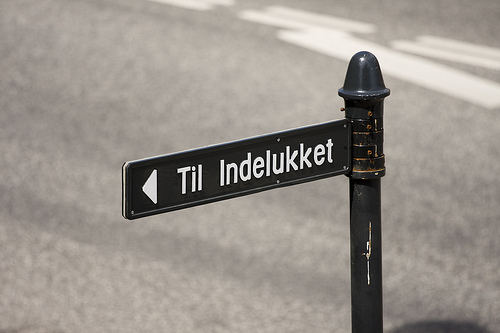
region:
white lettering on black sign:
[97, 103, 345, 235]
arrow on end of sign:
[110, 115, 340, 215]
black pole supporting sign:
[330, 40, 385, 326]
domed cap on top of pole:
[320, 45, 392, 100]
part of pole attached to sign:
[331, 82, 386, 183]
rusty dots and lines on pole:
[340, 90, 387, 180]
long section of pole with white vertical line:
[340, 172, 390, 327]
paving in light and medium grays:
[62, 30, 227, 125]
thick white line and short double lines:
[187, 2, 492, 117]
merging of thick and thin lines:
[198, 5, 394, 53]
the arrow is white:
[148, 163, 153, 221]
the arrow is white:
[138, 168, 157, 203]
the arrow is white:
[144, 176, 157, 198]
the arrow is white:
[143, 186, 168, 211]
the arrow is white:
[148, 173, 169, 200]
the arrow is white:
[153, 180, 165, 205]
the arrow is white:
[148, 183, 165, 196]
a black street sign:
[118, 121, 354, 226]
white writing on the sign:
[173, 137, 341, 199]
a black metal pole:
[336, 48, 404, 331]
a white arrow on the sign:
[138, 160, 162, 209]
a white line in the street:
[271, 16, 498, 118]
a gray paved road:
[1, 0, 499, 330]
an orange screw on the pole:
[363, 105, 378, 119]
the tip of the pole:
[332, 35, 397, 106]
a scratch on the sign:
[358, 217, 377, 288]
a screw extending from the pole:
[337, 102, 349, 115]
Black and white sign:
[104, 98, 341, 261]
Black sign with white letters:
[117, 103, 336, 250]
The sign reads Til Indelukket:
[118, 102, 341, 238]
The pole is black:
[336, 47, 396, 332]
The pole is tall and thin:
[342, 33, 409, 324]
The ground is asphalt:
[54, 19, 481, 326]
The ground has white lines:
[163, 17, 484, 229]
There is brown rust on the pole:
[335, 41, 387, 199]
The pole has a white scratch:
[345, 190, 405, 320]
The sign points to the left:
[99, 65, 360, 267]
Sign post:
[114, 48, 399, 325]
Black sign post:
[120, 47, 400, 332]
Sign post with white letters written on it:
[120, 48, 393, 329]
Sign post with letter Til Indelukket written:
[117, 49, 386, 331]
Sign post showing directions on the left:
[122, 49, 394, 330]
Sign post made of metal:
[121, 48, 393, 331]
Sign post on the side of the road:
[123, 50, 393, 330]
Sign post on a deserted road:
[122, 50, 392, 328]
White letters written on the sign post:
[119, 48, 394, 328]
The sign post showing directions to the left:
[119, 48, 393, 330]